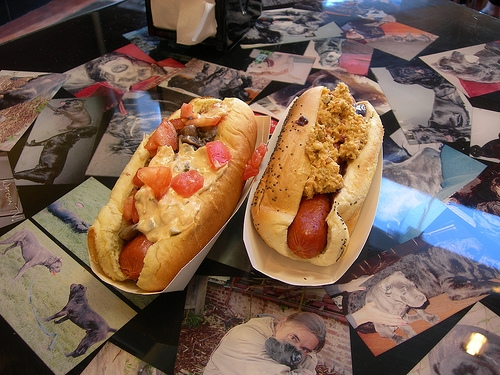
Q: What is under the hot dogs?
A: Pictures.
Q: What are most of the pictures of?
A: Black dogs.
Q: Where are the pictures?
A: Spread over the table.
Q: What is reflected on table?
A: Light.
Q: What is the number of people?
A: Zero.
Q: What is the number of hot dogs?
A: Two.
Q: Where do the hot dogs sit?
A: Inside buns.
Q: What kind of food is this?
A: Hot dogs.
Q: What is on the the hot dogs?
A: Condiments.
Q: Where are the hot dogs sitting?
A: Paper holders.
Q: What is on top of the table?
A: Photographs.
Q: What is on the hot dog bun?
A: Seeds.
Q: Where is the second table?
A: Upper left hand corner.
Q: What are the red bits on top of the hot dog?
A: Tomato.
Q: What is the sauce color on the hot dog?
A: Orange.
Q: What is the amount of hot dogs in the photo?
A: Two.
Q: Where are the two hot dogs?
A: Table.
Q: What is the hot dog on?
A: Tray.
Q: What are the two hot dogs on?
A: Plates.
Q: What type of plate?
A: Paper.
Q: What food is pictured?
A: Hot dogs.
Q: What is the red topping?
A: Tomato.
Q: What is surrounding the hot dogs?
A: Photographs.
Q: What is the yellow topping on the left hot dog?
A: Nacho cheese.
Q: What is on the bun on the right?
A: Seeds.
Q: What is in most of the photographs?
A: Two dogs.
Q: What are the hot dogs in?
A: Cardboard containers.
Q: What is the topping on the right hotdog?
A: Mustard.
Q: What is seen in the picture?
A: Hot dog.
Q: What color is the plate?
A: White.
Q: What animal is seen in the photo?
A: Dog.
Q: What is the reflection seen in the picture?
A: Light.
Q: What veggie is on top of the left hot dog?
A: Tomato.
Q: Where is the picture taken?
A: In a restaurant.